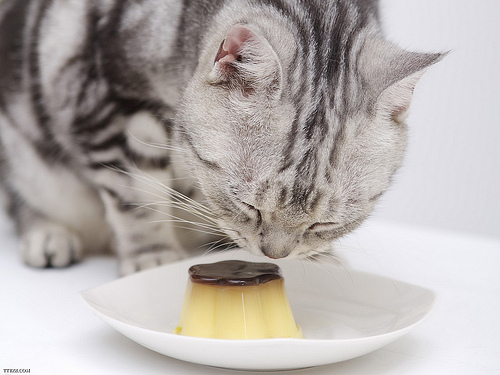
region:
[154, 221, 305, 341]
small custard on plate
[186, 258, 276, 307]
brown top on custard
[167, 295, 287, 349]
off white base on custard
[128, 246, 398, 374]
plate is small and white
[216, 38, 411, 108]
cat has grey ears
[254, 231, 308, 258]
cat has grey nose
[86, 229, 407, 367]
white plate on white table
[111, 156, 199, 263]
cat has striped paws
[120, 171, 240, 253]
cat has grey whiskers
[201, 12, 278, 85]
cat has pink spots in ears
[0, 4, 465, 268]
a cat sniffing at a dish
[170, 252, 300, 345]
a dessert on a dish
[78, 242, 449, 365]
the dish is white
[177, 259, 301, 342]
the jello is cream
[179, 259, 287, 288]
the top is chocolate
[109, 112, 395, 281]
the cat whiskers are white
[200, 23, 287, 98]
the cat ear is pink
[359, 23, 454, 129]
the cat has a right ear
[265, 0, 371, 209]
stripes on the cat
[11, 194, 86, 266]
a cat paw on the table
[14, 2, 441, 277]
a gray and silver cat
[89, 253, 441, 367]
a white saucer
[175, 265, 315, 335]
a pudding in the saucer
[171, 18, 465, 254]
a silver and gray cat head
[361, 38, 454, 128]
a left cat ear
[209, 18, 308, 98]
a right cat ear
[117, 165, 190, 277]
a right cat paw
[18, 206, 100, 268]
a right rear paw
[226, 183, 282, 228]
a right cat eye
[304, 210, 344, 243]
a left cat eye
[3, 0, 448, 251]
gray and black striped cat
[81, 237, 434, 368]
white plate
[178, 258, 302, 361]
yellow and brown food on a white plate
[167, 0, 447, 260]
striped cat sniffing some food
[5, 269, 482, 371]
white plate of food on a white surface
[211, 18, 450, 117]
two cat ears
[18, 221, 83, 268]
cat's back paw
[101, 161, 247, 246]
white whiskers on a cat's face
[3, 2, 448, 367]
cat sitting on a white surface near a plate of food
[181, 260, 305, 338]
flower shaped tan and brown food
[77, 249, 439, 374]
food in a white bowl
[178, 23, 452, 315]
cat sniffing the food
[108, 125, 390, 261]
white and gray whiskers on the cat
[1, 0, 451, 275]
black, gray and white cat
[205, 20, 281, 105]
inside of cat's ears are pink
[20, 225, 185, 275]
cats paws on the floor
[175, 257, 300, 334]
brown and yellow food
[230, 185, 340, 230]
cat's eyes looking down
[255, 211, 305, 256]
nose of the cat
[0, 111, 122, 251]
cat's tail curled around it's leg